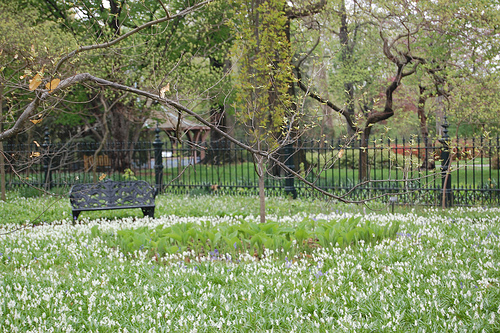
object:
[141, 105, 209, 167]
gazebo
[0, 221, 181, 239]
flowers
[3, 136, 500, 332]
property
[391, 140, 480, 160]
plants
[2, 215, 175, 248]
wildflowers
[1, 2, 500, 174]
background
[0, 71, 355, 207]
branch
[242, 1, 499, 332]
right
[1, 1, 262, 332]
left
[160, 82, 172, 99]
object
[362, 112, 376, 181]
brown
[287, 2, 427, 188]
tree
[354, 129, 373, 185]
trunk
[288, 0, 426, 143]
branches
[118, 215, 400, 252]
patch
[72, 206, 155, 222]
legs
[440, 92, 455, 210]
pole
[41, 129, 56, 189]
pole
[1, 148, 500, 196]
field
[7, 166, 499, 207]
grass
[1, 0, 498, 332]
outdoor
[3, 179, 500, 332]
park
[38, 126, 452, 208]
posts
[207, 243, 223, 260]
flowers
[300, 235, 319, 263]
flowers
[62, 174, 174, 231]
park bench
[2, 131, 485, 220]
fence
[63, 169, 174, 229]
bench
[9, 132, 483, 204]
fence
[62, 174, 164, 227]
bench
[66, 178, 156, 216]
bench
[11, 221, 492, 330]
grass